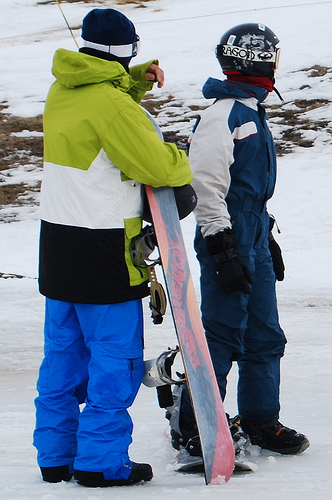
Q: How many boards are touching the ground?
A: 1.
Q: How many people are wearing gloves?
A: 1.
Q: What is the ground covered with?
A: Snow.